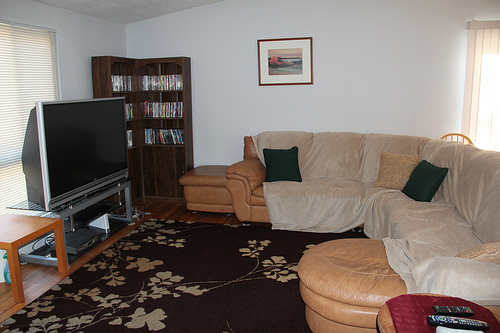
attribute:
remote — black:
[434, 295, 467, 325]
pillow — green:
[402, 158, 445, 203]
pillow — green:
[263, 147, 302, 179]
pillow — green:
[375, 151, 418, 188]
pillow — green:
[455, 241, 497, 262]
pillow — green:
[262, 145, 302, 183]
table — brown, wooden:
[0, 213, 68, 304]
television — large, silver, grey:
[20, 95, 129, 211]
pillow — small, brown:
[374, 150, 423, 192]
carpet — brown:
[88, 234, 298, 308]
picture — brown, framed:
[256, 35, 316, 87]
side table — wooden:
[1, 212, 73, 303]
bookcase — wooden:
[92, 55, 146, 200]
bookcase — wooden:
[137, 56, 193, 194]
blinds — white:
[20, 45, 47, 88]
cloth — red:
[387, 290, 499, 330]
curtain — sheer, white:
[465, 20, 497, 143]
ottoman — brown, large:
[301, 235, 402, 332]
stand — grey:
[9, 181, 135, 266]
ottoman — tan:
[300, 230, 415, 331]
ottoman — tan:
[181, 154, 232, 214]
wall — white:
[127, 3, 462, 200]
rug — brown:
[2, 219, 366, 331]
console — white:
[85, 212, 112, 234]